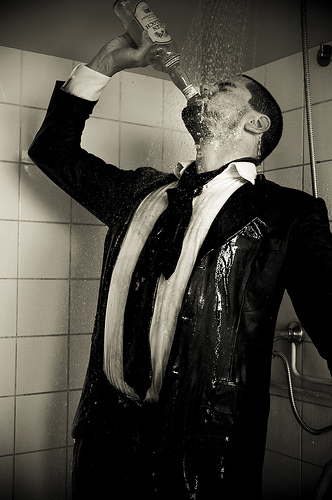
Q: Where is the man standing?
A: Shower.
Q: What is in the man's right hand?
A: Bottle.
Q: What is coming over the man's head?
A: Water.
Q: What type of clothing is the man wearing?
A: Suit and tie.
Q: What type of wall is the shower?
A: Tiled.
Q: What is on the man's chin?
A: Beard.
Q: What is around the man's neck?
A: Tie.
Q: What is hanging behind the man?
A: Shower head cord.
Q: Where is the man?
A: In the shower.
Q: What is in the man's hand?
A: Alcoholic beverage.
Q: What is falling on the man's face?
A: Water.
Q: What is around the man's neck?
A: Necktie.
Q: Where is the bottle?
A: In the man's hand.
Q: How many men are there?
A: One.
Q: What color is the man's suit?
A: Black.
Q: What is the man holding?
A: A bottle.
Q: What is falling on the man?
A: Water.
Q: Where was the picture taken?
A: In a bathroom.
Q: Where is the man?
A: In the shower.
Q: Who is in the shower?
A: The man.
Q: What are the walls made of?
A: Tile.